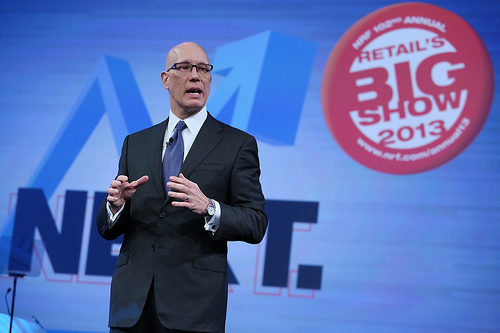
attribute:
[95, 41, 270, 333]
man — dictating, bald, standing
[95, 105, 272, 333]
suit — black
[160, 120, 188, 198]
tie — purple, navy blue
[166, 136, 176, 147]
microphone — black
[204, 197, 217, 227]
watch — silver, round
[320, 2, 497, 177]
sign — large, round, red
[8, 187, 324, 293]
writing — dark blue, blue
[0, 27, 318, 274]
arrow — blue, pointing up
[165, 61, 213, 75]
glasses — thick rimmed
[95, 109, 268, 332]
jacket — black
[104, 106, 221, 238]
shirt — white, collared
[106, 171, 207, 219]
hands — gesturing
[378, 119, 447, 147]
year — 2013